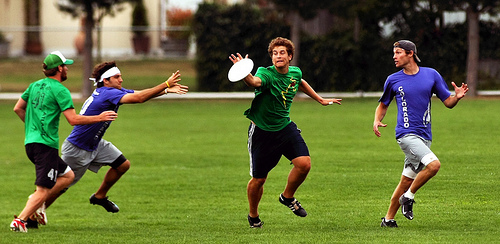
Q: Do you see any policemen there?
A: No, there are no policemen.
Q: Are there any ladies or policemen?
A: No, there are no policemen or ladies.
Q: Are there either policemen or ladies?
A: No, there are no policemen or ladies.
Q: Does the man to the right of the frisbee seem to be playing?
A: Yes, the man is playing.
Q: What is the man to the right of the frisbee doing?
A: The man is playing.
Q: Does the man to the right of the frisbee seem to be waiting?
A: No, the man is playing.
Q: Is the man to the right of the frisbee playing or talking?
A: The man is playing.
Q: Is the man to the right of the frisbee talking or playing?
A: The man is playing.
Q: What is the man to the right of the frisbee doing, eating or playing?
A: The man is playing.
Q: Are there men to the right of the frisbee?
A: Yes, there is a man to the right of the frisbee.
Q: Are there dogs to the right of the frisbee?
A: No, there is a man to the right of the frisbee.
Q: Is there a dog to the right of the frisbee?
A: No, there is a man to the right of the frisbee.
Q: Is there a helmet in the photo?
A: No, there are no helmets.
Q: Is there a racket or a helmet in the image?
A: No, there are no helmets or rackets.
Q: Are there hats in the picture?
A: Yes, there is a hat.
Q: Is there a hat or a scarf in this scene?
A: Yes, there is a hat.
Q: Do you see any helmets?
A: No, there are no helmets.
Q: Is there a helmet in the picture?
A: No, there are no helmets.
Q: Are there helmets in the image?
A: No, there are no helmets.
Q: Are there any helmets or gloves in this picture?
A: No, there are no helmets or gloves.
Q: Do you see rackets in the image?
A: No, there are no rackets.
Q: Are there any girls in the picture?
A: No, there are no girls.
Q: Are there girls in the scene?
A: No, there are no girls.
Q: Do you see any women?
A: No, there are no women.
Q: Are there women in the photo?
A: No, there are no women.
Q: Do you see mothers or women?
A: No, there are no women or mothers.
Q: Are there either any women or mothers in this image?
A: No, there are no women or mothers.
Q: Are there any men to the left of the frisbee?
A: Yes, there is a man to the left of the frisbee.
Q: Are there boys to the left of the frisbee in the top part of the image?
A: No, there is a man to the left of the frisbee.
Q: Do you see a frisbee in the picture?
A: Yes, there is a frisbee.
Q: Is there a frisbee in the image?
A: Yes, there is a frisbee.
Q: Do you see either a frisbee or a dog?
A: Yes, there is a frisbee.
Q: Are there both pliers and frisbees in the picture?
A: No, there is a frisbee but no pliers.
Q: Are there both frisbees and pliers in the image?
A: No, there is a frisbee but no pliers.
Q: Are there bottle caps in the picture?
A: No, there are no bottle caps.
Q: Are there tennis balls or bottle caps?
A: No, there are no bottle caps or tennis balls.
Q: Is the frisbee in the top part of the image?
A: Yes, the frisbee is in the top of the image.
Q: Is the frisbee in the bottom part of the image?
A: No, the frisbee is in the top of the image.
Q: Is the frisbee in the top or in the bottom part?
A: The frisbee is in the top of the image.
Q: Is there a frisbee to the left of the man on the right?
A: Yes, there is a frisbee to the left of the man.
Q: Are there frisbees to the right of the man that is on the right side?
A: No, the frisbee is to the left of the man.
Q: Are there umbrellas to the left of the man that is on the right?
A: No, there is a frisbee to the left of the man.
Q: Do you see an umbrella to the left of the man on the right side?
A: No, there is a frisbee to the left of the man.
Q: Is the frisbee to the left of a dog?
A: No, the frisbee is to the left of a man.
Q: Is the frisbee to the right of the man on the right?
A: No, the frisbee is to the left of the man.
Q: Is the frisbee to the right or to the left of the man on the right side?
A: The frisbee is to the left of the man.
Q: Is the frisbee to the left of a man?
A: No, the frisbee is to the right of a man.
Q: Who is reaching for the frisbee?
A: The man is reaching for the frisbee.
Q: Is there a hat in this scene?
A: Yes, there is a hat.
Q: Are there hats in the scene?
A: Yes, there is a hat.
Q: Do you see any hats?
A: Yes, there is a hat.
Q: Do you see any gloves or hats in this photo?
A: Yes, there is a hat.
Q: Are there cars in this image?
A: No, there are no cars.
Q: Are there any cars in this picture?
A: No, there are no cars.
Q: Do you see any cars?
A: No, there are no cars.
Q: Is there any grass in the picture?
A: Yes, there is grass.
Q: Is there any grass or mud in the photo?
A: Yes, there is grass.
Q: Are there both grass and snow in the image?
A: No, there is grass but no snow.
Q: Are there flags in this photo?
A: No, there are no flags.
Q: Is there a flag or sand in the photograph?
A: No, there are no flags or sand.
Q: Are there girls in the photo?
A: No, there are no girls.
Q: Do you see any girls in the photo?
A: No, there are no girls.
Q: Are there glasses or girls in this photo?
A: No, there are no girls or glasses.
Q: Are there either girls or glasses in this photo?
A: No, there are no girls or glasses.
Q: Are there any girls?
A: No, there are no girls.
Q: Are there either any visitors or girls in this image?
A: No, there are no girls or visitors.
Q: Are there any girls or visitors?
A: No, there are no girls or visitors.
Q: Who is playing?
A: The man is playing.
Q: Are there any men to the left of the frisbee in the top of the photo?
A: Yes, there is a man to the left of the frisbee.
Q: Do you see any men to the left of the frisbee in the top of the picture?
A: Yes, there is a man to the left of the frisbee.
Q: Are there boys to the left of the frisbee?
A: No, there is a man to the left of the frisbee.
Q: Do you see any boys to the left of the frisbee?
A: No, there is a man to the left of the frisbee.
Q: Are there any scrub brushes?
A: No, there are no scrub brushes.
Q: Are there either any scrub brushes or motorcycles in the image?
A: No, there are no scrub brushes or motorcycles.